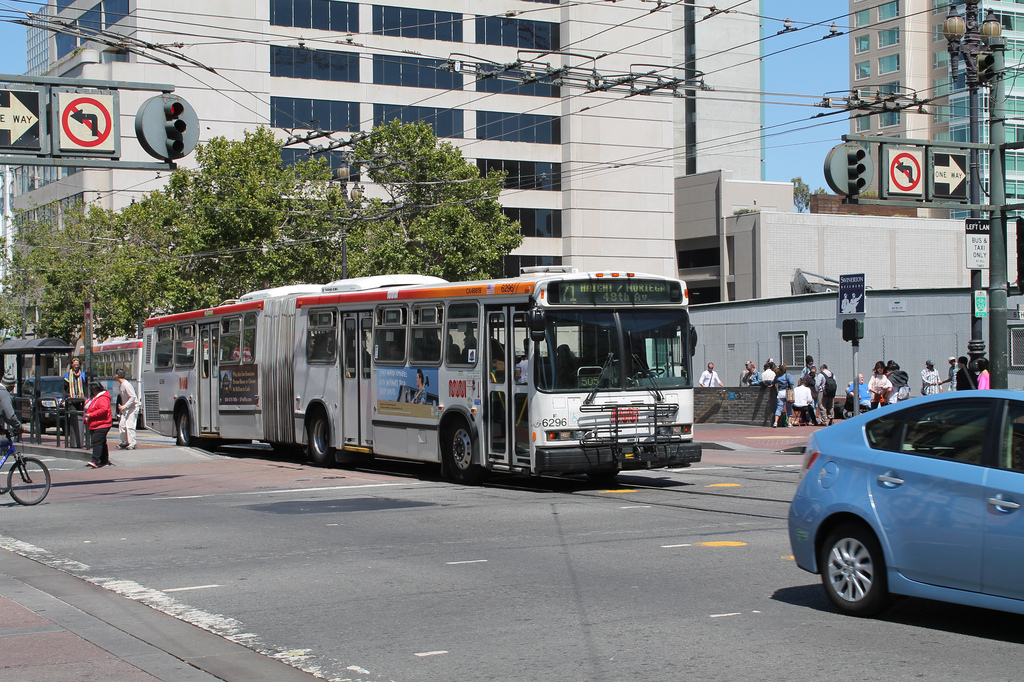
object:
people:
[772, 365, 794, 428]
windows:
[270, 45, 361, 83]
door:
[482, 303, 529, 473]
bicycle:
[0, 428, 51, 505]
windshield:
[535, 309, 693, 394]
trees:
[122, 116, 525, 311]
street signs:
[824, 144, 968, 198]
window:
[477, 158, 562, 191]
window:
[373, 104, 464, 139]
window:
[270, 96, 360, 132]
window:
[475, 15, 561, 51]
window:
[674, 236, 736, 305]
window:
[271, 148, 361, 182]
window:
[478, 207, 562, 237]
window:
[55, 0, 129, 59]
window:
[878, 54, 900, 77]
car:
[788, 389, 1024, 615]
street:
[0, 423, 1024, 682]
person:
[699, 362, 724, 387]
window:
[270, 45, 360, 83]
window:
[269, 0, 359, 33]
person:
[868, 361, 887, 409]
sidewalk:
[694, 419, 857, 454]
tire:
[822, 524, 894, 612]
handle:
[83, 382, 112, 468]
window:
[477, 110, 561, 145]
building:
[0, 0, 761, 340]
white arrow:
[0, 91, 40, 145]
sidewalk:
[0, 433, 213, 466]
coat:
[83, 389, 112, 429]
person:
[848, 373, 882, 409]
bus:
[143, 265, 702, 484]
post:
[946, 0, 1001, 374]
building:
[674, 170, 1016, 428]